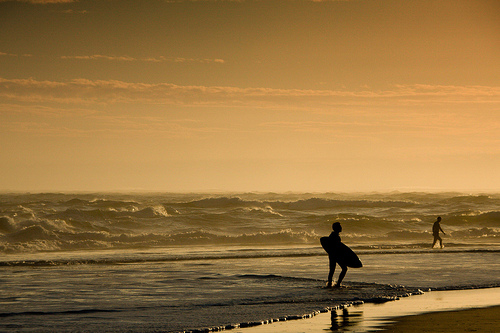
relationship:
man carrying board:
[320, 215, 369, 286] [320, 234, 367, 270]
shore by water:
[0, 256, 500, 332] [3, 232, 498, 253]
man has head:
[320, 215, 369, 286] [330, 219, 347, 231]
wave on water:
[3, 189, 483, 247] [3, 232, 498, 253]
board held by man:
[320, 234, 367, 270] [320, 215, 369, 286]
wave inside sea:
[3, 189, 483, 247] [2, 190, 499, 294]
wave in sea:
[3, 189, 483, 247] [2, 190, 499, 294]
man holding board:
[320, 215, 369, 286] [320, 234, 367, 270]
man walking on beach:
[320, 215, 369, 286] [3, 245, 495, 329]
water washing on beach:
[3, 232, 498, 253] [3, 245, 495, 329]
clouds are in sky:
[1, 24, 496, 179] [1, 4, 499, 186]